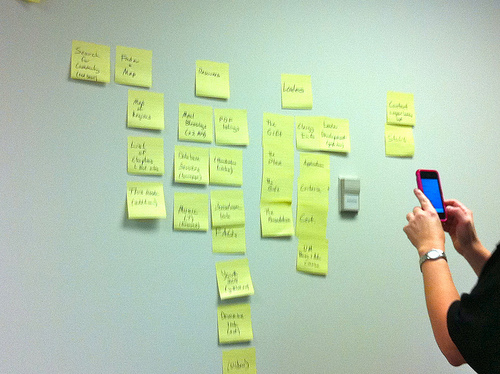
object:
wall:
[25, 115, 69, 182]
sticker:
[69, 37, 112, 83]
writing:
[84, 63, 99, 74]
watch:
[420, 250, 445, 266]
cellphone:
[415, 168, 448, 220]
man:
[402, 187, 499, 194]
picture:
[420, 178, 441, 211]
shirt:
[446, 239, 498, 372]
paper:
[128, 180, 168, 218]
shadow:
[124, 218, 156, 232]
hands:
[402, 188, 475, 253]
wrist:
[456, 243, 485, 258]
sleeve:
[446, 303, 484, 373]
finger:
[413, 186, 437, 212]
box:
[335, 174, 361, 212]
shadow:
[342, 209, 357, 219]